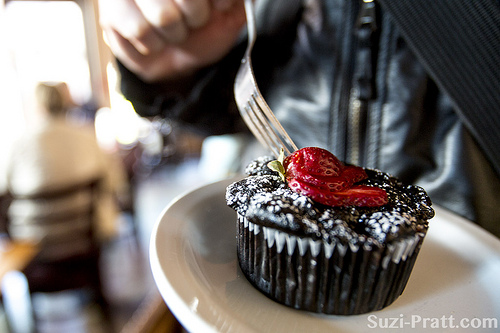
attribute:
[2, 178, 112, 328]
wooden chair — dark brown